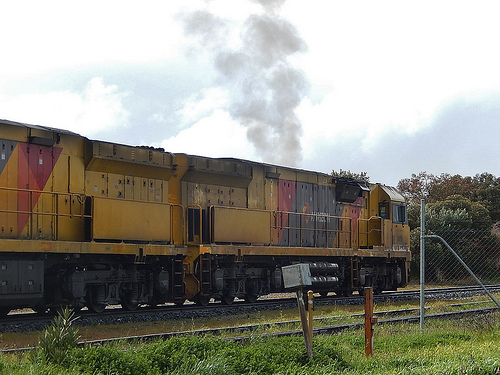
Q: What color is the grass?
A: Green.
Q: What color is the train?
A: Yellow.